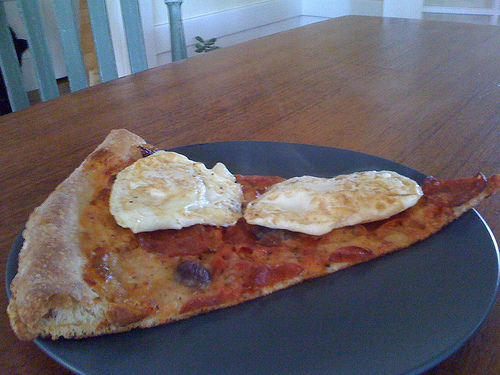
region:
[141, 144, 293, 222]
Eggs on top of pizza.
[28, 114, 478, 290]
One slice of pizza on plate.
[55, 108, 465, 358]
Plate on the table.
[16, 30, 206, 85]
A blue chair next to table.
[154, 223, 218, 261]
Pepperoni on the pizza.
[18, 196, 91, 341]
Crust of the pizza.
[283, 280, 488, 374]
The plate is gray.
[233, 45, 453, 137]
The table is wooden.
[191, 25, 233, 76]
A plant in the corner floor.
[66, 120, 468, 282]
One slice of pizza with eggs on top.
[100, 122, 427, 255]
THE EGGS ARE ON THE PIZZA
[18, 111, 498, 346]
THE PIZZA IS ON THE PLATE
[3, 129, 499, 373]
THE PLATE IS ON THE TABLE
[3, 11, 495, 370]
THE TABLE IS WOODEN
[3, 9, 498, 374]
THE TABLE IS BROWN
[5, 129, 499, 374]
THE PLATE IS ROUND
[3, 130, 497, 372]
THE PLATE IS BLUE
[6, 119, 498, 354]
THE PIZZA HAS CHEESE ON IT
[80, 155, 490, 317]
THE PIZZA HAS PEPPERONI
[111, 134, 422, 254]
THE EGGS ARE FRIED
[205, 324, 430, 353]
the plate is balck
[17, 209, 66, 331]
the crust is brown in color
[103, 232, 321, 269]
the pizza is brown in color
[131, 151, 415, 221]
the egges are two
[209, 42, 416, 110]
the table is wooden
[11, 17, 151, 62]
the cjhir is painted blue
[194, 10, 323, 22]
the wall is white in color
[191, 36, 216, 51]
the plant is in house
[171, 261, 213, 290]
the pizza is made of meat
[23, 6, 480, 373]
the scene is indoor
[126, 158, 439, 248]
the eggs are two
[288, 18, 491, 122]
the surface is wooden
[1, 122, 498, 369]
the plate is grey in color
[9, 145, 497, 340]
the pizza is triangular in colar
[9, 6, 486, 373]
the scene is indoors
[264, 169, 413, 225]
the eggs are white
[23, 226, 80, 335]
the crust is brown in color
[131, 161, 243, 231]
the eggs is half cooked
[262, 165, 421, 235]
the eggg is half ccooked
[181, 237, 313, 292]
the topping is red in color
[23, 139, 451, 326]
a slice of pizza on a blue plate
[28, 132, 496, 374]
a round blue plate with a slice of pizza on top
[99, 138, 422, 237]
fried egg whites on top of the pizza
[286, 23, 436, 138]
brown wood surface of the dining table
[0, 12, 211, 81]
blue wood slats of the back of a chair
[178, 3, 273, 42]
white walls of the dining room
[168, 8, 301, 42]
wood trim on the dining room wall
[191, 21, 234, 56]
the top of a plant on the floor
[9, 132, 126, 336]
the brown baked crust of the pizza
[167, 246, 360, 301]
small pieces of pepperoni on the pizza